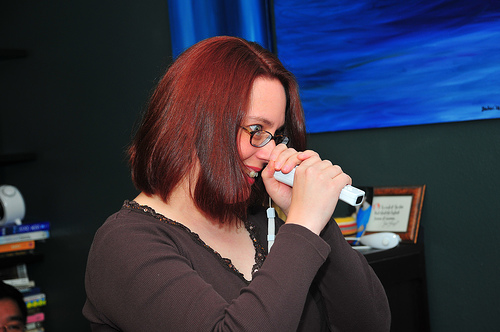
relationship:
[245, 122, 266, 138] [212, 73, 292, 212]
eyes on face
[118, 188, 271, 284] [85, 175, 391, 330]
neckline on shirt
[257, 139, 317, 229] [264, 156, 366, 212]
hands gripping telescope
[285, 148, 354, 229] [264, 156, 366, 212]
hands gripping telescope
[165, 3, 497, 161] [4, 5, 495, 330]
abstract on wall